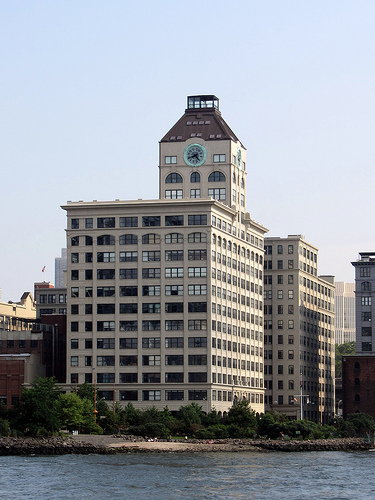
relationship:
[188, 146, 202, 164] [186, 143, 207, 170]
gray black and green clock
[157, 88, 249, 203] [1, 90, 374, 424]
this is a several buildings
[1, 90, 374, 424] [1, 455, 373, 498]
several buildings by water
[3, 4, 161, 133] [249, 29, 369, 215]
blue sky with white clouds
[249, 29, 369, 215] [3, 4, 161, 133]
white clouds with blue sky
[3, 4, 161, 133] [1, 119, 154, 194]
blue sky with white clouds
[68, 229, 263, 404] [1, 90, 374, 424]
many windows on a several buildings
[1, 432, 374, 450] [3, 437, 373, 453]
coastline that rocky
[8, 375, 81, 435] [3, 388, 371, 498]
green along coast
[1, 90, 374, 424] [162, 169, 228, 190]
several buildings with tall circular windows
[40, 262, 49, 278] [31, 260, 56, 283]
flag in distance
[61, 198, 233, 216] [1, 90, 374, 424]
roof to a several buildings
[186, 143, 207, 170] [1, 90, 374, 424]
clock is located up several buildings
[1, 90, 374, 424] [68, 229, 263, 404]
several buildings with windows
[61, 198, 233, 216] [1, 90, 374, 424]
rooftop on th several buildings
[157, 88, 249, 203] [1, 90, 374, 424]
tall tower attached to several buildings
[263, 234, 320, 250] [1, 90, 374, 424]
roof of a several buildings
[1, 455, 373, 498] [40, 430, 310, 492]
dark water in forefront dark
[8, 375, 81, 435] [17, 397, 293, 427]
green in forefront are green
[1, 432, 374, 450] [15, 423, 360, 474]
coastline has rocks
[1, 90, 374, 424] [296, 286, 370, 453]
several buildings on right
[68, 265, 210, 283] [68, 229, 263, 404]
row of many windows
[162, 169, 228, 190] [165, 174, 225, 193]
three windows are half-circles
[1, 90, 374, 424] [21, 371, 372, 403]
buildings are right on edge of a lake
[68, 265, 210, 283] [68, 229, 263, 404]
rows of many windows